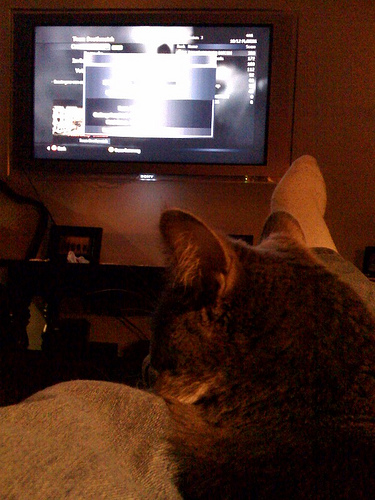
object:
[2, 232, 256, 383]
stand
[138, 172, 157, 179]
logo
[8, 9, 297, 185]
television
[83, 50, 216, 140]
box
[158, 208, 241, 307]
furry ears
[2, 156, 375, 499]
person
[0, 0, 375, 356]
wall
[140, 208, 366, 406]
head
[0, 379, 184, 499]
couch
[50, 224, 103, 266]
frame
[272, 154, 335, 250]
sock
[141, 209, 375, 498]
animal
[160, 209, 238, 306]
ear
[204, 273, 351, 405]
neck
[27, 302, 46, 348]
items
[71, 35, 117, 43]
writing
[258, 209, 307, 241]
ear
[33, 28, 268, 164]
screen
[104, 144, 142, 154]
button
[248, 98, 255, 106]
numbers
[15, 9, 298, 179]
frame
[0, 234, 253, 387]
table